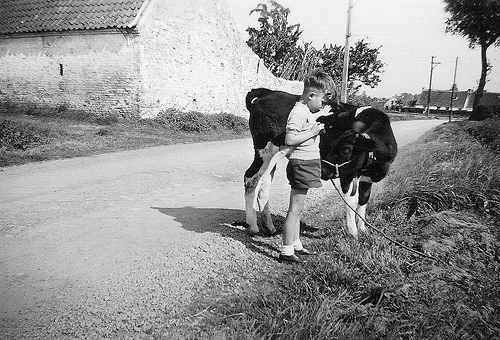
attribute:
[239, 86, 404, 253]
cow — white, black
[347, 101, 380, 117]
patch — white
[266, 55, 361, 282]
boy — little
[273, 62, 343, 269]
child — small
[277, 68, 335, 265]
boy — little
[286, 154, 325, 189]
shorts — dark colored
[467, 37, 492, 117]
branch — crooked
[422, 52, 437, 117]
pole — tall wooden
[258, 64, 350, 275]
boy — little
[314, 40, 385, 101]
tree — tall, shady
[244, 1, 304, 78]
tree — tall, shady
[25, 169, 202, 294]
road — empty, gravel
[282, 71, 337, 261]
boy — little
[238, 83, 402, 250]
calf — white, black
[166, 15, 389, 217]
boy — little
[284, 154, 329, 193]
shorts — casual , cotton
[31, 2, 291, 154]
building — white stone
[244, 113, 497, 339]
vegetation — grassy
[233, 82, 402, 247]
cow — black, white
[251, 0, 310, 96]
tree — tall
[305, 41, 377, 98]
tree — tall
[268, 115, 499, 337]
vegetation — grassy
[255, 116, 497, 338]
grassy vegetation — grassy 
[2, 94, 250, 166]
grassy vegetation — grassy 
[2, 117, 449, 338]
road — country dirt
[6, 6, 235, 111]
building — old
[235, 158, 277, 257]
legs — black, white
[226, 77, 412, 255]
cow — black and white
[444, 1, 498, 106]
tree — tall, shady, large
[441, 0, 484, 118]
tree — tall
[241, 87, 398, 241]
calf — black, white